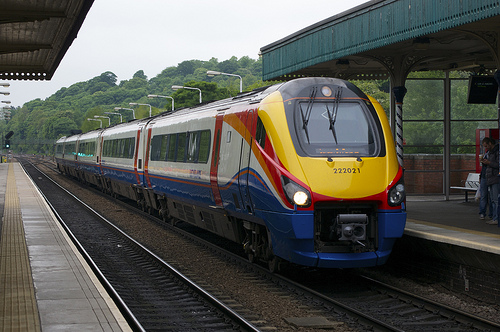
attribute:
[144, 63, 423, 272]
train — yellow, red, blue, white, orange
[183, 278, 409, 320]
tracks — black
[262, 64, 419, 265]
front — yellow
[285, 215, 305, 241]
paint — blue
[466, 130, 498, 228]
people — standing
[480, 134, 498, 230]
man — standing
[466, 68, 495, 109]
sign — black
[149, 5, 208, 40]
sky — clear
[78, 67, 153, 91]
trees — green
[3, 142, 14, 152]
light — green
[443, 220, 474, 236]
line — yellow, thick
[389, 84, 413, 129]
pole — striped